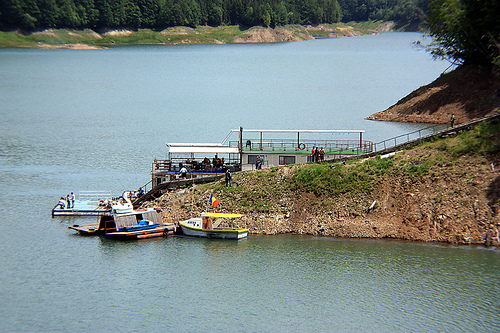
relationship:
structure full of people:
[163, 142, 240, 169] [180, 155, 230, 169]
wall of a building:
[242, 154, 354, 171] [152, 128, 365, 187]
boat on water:
[175, 194, 249, 240] [2, 19, 498, 329]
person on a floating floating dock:
[63, 192, 71, 209] [52, 185, 123, 220]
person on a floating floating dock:
[67, 189, 76, 206] [52, 185, 123, 220]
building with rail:
[238, 144, 370, 170] [227, 139, 376, 155]